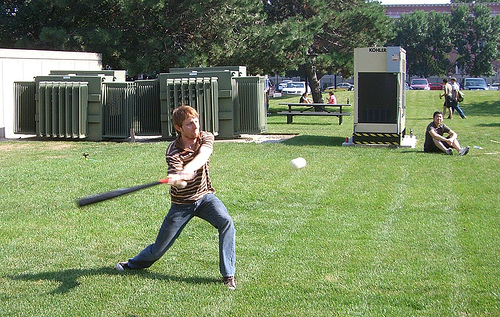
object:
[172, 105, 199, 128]
hair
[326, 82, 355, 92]
cars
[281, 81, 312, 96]
car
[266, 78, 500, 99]
parking lot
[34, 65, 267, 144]
machine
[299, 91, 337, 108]
people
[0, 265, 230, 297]
shadow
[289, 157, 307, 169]
ball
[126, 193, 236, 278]
jeans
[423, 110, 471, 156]
man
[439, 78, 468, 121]
people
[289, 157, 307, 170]
baseball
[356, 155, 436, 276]
grass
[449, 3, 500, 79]
tree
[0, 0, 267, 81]
trees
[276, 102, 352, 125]
picnic table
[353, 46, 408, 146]
power boxes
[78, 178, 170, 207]
bat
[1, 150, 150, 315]
grass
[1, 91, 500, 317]
ground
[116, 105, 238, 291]
man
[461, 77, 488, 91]
car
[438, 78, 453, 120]
person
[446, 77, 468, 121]
person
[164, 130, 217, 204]
shirt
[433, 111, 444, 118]
hair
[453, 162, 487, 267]
grass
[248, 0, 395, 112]
tree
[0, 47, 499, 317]
park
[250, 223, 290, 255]
patch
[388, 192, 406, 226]
patch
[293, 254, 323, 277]
patch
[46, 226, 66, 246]
patch